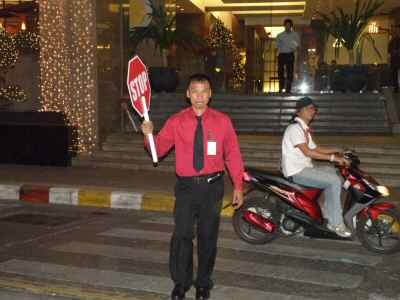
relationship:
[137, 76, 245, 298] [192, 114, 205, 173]
man wearing black tie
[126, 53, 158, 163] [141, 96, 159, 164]
sign on handle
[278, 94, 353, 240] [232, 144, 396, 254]
man sitting on motorcycle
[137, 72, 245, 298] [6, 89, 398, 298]
man walking down steps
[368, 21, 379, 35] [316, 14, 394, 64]
light on wall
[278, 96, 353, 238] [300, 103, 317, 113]
man wearing glasses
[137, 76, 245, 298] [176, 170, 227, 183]
man wearing black belt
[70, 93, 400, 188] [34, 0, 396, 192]
steps to building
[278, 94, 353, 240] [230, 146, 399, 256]
man on motocycle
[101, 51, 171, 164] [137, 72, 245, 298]
sign in man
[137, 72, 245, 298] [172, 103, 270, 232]
man with shirt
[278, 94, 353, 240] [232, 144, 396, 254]
man on motorcycle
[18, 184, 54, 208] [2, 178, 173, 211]
block on curb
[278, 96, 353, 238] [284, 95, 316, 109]
man wearing hat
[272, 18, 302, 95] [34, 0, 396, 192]
man walking out building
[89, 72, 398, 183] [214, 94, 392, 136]
steps in front building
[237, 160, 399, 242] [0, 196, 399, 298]
motorcycle on road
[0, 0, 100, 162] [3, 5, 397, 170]
shubbery outside building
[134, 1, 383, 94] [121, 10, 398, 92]
plants in lobby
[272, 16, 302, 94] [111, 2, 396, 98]
man standing in lobby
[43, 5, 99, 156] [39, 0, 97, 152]
lights on post